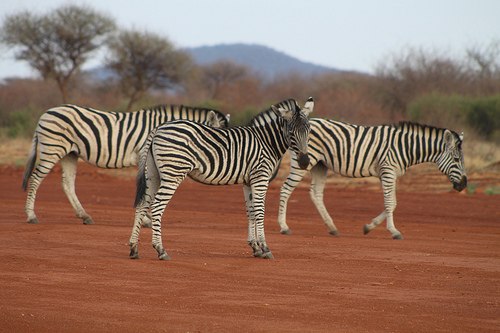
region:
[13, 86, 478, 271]
a group of three zebras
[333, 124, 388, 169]
black and white stripes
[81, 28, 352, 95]
hill in the background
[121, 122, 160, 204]
long striped tail with black hair at the end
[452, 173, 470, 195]
solid black snout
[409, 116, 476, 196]
head pointed down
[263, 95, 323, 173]
head tilted to the side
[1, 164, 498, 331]
rust colored clay ground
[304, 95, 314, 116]
pointy ear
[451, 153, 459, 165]
small black eye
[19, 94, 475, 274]
Three zebras walking.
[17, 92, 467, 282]
The zebras are black and white.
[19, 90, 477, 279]
One zebra is looking at the camera.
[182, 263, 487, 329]
The ground is dirt.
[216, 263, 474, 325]
The dirt is brown.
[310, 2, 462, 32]
The sky is blue.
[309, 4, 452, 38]
The sky is overcast.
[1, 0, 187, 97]
Trees are in the background.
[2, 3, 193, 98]
The trees are brown.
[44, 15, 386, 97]
A mountain is in the distance.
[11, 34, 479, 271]
three zebras in a group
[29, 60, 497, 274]
three black and white zebras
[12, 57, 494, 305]
black and white zebras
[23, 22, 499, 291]
zebras standing in the dirt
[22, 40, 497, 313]
zebras standing on the red dirt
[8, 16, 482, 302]
zebras standing on red clay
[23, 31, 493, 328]
zebras playing in the dirt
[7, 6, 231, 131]
trees in the distance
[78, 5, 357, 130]
mountains in the distance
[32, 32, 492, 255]
a black and white zebra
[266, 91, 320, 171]
the head of a zebra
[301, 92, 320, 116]
the ear of a zebra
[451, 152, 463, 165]
the eye of a zebra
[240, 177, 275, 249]
the front legs of a zebra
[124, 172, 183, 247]
the hind legs of a zebra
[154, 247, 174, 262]
the hoof of a zebra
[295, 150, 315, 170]
the nose of a zebra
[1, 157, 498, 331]
a patch of brown dirt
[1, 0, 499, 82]
a pale blue sky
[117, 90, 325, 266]
a black and white zebra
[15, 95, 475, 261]
Three zebras standing near each other.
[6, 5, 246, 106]
Trees in the background.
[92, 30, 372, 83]
A mountain in the distance.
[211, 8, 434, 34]
The sky is light blue.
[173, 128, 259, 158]
The zebra has black and white stripes.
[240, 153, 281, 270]
The zebra has two front legs.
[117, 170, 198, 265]
The zebra has two hind legs.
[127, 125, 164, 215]
The zebra has a tail.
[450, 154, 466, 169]
An eye on the zebra.